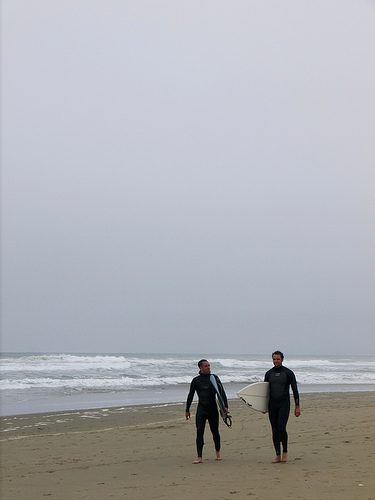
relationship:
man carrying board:
[266, 351, 301, 463] [234, 379, 272, 413]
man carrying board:
[184, 356, 231, 465] [214, 396, 233, 427]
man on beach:
[266, 351, 301, 463] [4, 393, 372, 496]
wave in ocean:
[6, 355, 128, 367] [4, 351, 374, 414]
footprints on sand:
[226, 487, 254, 499] [4, 393, 372, 496]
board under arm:
[234, 379, 272, 413] [264, 369, 268, 378]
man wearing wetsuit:
[266, 351, 301, 463] [262, 366, 298, 457]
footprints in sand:
[226, 487, 254, 499] [4, 393, 372, 496]